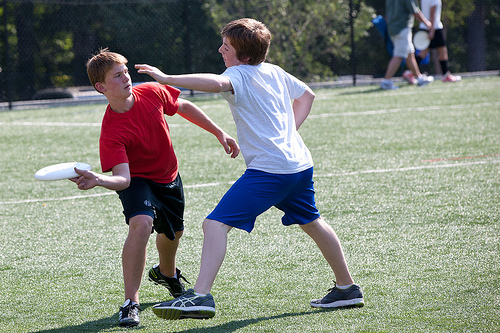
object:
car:
[33, 85, 105, 100]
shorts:
[206, 164, 322, 235]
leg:
[189, 167, 283, 299]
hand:
[66, 166, 98, 191]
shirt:
[98, 79, 182, 186]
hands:
[216, 132, 242, 160]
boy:
[65, 47, 238, 328]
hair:
[82, 45, 130, 95]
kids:
[133, 15, 364, 319]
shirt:
[219, 61, 314, 177]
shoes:
[305, 280, 372, 310]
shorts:
[112, 170, 188, 242]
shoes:
[112, 297, 145, 329]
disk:
[33, 161, 96, 181]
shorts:
[385, 26, 414, 59]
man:
[403, 0, 460, 87]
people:
[377, 0, 435, 91]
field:
[0, 70, 499, 333]